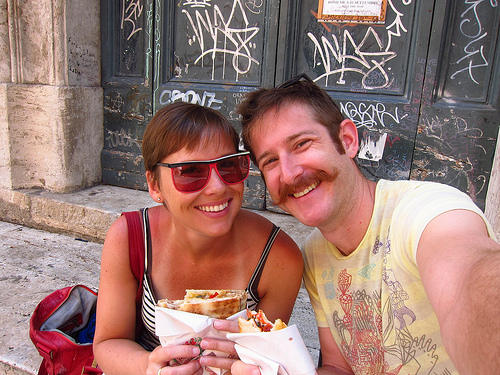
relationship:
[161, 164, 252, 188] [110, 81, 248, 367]
glasses on woman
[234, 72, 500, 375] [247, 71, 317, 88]
man has a pair sunglasses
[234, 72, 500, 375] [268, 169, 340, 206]
man has a mustache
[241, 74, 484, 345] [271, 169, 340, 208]
man with a mustache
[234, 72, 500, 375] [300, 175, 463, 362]
man wearing  a shirt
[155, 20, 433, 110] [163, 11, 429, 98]
graffiti on a door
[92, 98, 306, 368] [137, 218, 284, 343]
woman wearing a tank top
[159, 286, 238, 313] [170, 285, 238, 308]
panini in a wrapper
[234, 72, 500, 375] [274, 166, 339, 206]
man with a mustache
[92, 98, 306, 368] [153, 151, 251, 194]
woman wearing glasses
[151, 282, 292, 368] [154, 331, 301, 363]
food wrapped in paper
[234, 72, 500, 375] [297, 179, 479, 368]
man in a shirt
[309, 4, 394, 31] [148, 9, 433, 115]
sign on a door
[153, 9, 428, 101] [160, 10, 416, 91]
doors with graffiti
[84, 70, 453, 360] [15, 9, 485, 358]
couple posing for a picture